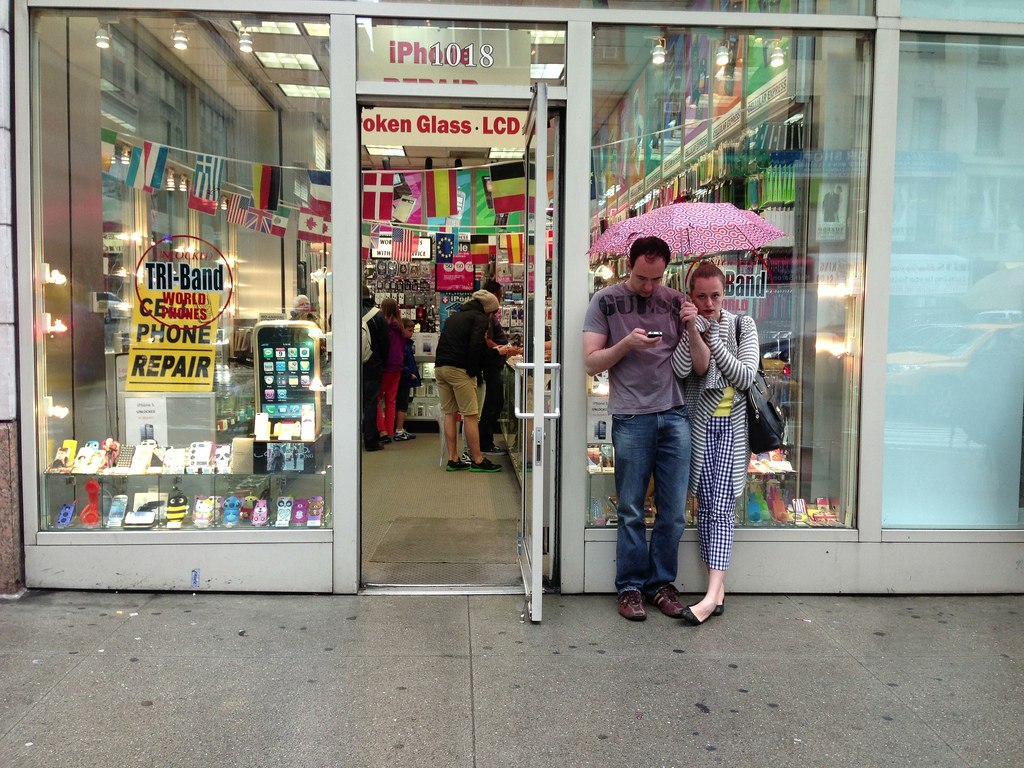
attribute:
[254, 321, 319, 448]
cell phone — large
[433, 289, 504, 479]
person — green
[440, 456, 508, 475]
shoes — black